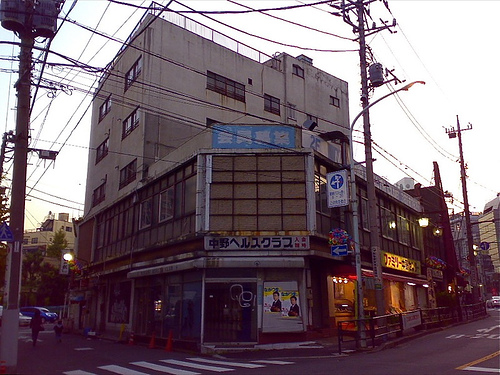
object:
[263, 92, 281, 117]
windows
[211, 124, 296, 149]
sign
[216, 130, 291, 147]
writing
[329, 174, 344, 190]
circle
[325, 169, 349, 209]
street sign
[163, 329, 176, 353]
cones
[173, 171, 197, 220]
window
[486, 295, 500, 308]
car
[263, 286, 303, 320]
poster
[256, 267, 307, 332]
wall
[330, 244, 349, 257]
sign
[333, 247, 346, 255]
arrow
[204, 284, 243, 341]
door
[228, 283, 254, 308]
graffiti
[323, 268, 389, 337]
store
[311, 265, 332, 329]
corner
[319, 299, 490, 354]
passage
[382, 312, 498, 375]
street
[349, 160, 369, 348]
pole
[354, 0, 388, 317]
pole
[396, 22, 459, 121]
wires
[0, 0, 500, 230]
sky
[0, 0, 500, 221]
background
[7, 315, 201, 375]
road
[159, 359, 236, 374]
lines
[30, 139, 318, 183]
wires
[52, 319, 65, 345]
child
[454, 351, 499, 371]
line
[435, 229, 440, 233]
lights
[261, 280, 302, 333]
window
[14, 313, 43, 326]
cars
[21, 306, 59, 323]
car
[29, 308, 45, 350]
mom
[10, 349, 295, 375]
pavement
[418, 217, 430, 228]
lamp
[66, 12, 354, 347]
building